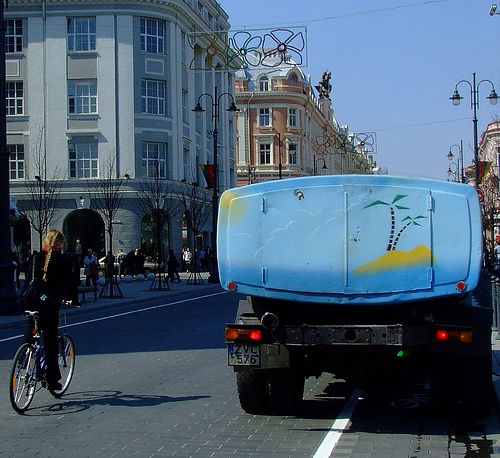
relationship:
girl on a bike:
[15, 229, 79, 391] [9, 309, 81, 413]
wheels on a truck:
[238, 372, 303, 416] [215, 172, 497, 415]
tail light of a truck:
[438, 330, 445, 340] [215, 172, 497, 415]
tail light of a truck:
[459, 330, 469, 342] [215, 172, 497, 415]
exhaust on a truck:
[257, 307, 285, 338] [203, 150, 499, 431]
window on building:
[65, 76, 100, 117] [1, 3, 233, 272]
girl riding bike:
[15, 229, 79, 391] [7, 296, 84, 416]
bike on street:
[7, 296, 84, 416] [1, 271, 498, 453]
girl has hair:
[15, 229, 79, 391] [35, 217, 65, 289]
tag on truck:
[227, 340, 265, 366] [215, 172, 497, 415]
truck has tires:
[219, 290, 480, 372] [238, 369, 304, 409]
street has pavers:
[1, 271, 498, 453] [220, 416, 311, 453]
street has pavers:
[1, 271, 498, 453] [121, 405, 230, 452]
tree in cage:
[137, 160, 183, 259] [142, 256, 173, 286]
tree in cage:
[176, 171, 213, 253] [192, 250, 212, 287]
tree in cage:
[91, 152, 123, 264] [99, 271, 126, 298]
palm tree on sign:
[362, 194, 428, 251] [259, 197, 441, 277]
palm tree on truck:
[367, 197, 420, 246] [224, 182, 490, 308]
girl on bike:
[15, 229, 79, 391] [17, 317, 69, 403]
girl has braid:
[16, 230, 79, 391] [42, 247, 52, 281]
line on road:
[280, 383, 367, 454] [2, 411, 492, 453]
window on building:
[145, 80, 166, 124] [239, 58, 381, 172]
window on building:
[4, 17, 25, 57] [1, 3, 233, 272]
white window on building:
[3, 80, 23, 116] [1, 3, 233, 272]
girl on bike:
[15, 229, 79, 391] [9, 299, 82, 414]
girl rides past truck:
[15, 229, 79, 391] [206, 177, 494, 440]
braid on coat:
[41, 235, 55, 284] [21, 249, 78, 305]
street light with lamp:
[466, 80, 490, 179] [479, 76, 499, 114]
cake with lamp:
[447, 62, 499, 172] [440, 79, 469, 110]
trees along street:
[11, 131, 216, 285] [1, 271, 498, 453]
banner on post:
[200, 160, 222, 186] [174, 76, 253, 299]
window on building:
[61, 129, 115, 177] [1, 3, 233, 272]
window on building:
[127, 124, 192, 178] [1, 3, 233, 272]